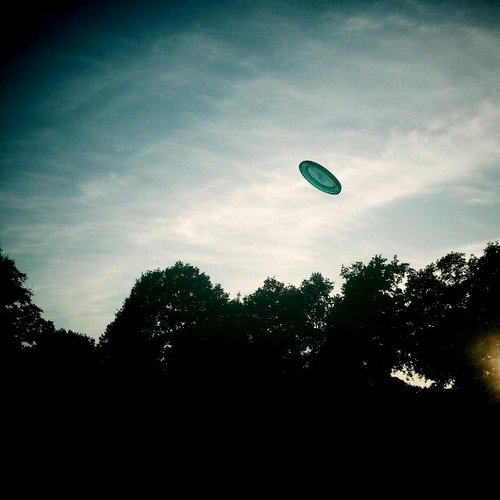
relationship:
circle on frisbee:
[306, 163, 340, 189] [275, 151, 424, 268]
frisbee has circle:
[298, 157, 343, 200] [306, 165, 335, 190]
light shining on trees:
[468, 328, 498, 384] [0, 246, 499, 390]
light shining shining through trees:
[388, 362, 457, 393] [0, 244, 499, 499]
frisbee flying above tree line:
[298, 160, 342, 197] [1, 238, 499, 345]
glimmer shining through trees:
[467, 327, 499, 379] [0, 244, 499, 499]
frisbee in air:
[298, 160, 342, 197] [21, 40, 479, 247]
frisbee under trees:
[298, 160, 342, 197] [0, 244, 499, 499]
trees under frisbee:
[0, 244, 499, 499] [298, 160, 342, 197]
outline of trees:
[1, 244, 499, 386] [0, 237, 497, 450]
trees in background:
[0, 244, 499, 499] [3, 177, 484, 383]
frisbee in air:
[298, 160, 342, 197] [3, 7, 498, 447]